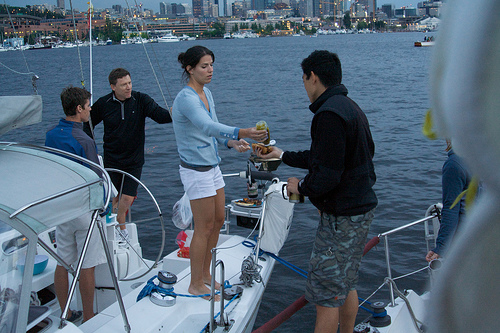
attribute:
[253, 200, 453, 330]
safety rail — stainless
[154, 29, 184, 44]
yacht — white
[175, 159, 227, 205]
shorts — white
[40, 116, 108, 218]
jacket — gray, blue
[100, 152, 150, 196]
shorts — black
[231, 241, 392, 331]
rope — blue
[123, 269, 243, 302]
rope — blue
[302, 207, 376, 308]
shorts — camoflauge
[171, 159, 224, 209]
shorts — white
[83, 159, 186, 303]
wheel — steering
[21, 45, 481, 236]
water — body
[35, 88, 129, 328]
man — young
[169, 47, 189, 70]
tail — pony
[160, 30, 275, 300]
woman — young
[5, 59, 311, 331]
boat — small, white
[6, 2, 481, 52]
skyline — city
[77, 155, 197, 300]
wheel — steering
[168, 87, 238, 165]
sweater — blue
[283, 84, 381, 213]
sweater — black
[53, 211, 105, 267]
shorts — white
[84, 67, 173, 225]
shorts — black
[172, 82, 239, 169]
sweater — long sleeved, blue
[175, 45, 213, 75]
hair — brown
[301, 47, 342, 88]
hair — black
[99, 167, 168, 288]
steering wheel — silver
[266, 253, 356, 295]
blue rope — tied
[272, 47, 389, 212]
man wearing — black fleece top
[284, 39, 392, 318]
man wearing — camouflage shorts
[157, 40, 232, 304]
woman wearing — short white shorts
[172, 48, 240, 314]
woman wearing — light blue cardigan